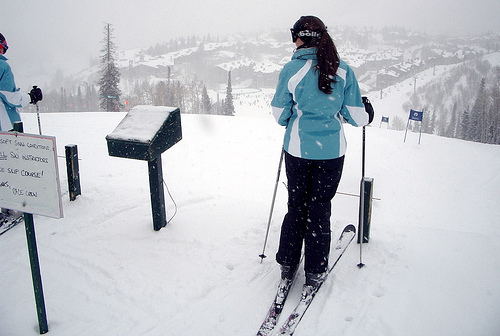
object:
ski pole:
[356, 96, 365, 268]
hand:
[31, 87, 43, 105]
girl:
[270, 15, 375, 286]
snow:
[1, 0, 500, 336]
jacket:
[271, 47, 369, 160]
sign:
[0, 131, 64, 335]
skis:
[253, 224, 357, 336]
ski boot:
[305, 272, 330, 287]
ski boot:
[280, 266, 298, 281]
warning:
[0, 133, 64, 220]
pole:
[24, 212, 51, 335]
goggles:
[290, 28, 325, 43]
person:
[0, 32, 43, 219]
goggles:
[0, 40, 8, 45]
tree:
[20, 20, 500, 146]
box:
[105, 105, 183, 162]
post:
[105, 104, 184, 231]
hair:
[293, 15, 341, 94]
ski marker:
[403, 109, 423, 145]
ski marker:
[379, 115, 389, 129]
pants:
[275, 149, 345, 274]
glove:
[27, 85, 43, 105]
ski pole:
[258, 144, 284, 263]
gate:
[282, 177, 381, 244]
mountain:
[32, 23, 500, 145]